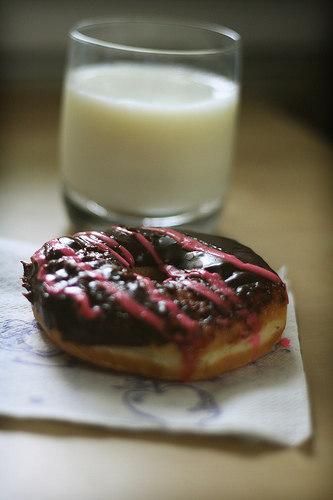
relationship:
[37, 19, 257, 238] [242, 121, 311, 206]
glass on table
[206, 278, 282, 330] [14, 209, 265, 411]
side of donut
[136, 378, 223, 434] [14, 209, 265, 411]
apple on napkin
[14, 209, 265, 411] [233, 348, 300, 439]
donut on napkin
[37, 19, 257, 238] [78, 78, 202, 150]
glass has millk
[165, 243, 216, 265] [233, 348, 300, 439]
icing on napkin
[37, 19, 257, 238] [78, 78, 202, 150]
glass of milk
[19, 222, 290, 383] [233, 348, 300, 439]
donut on napkin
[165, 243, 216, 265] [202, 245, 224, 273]
icing has light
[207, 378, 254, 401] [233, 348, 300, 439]
crumb on napkin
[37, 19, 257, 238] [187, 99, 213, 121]
glass of milk